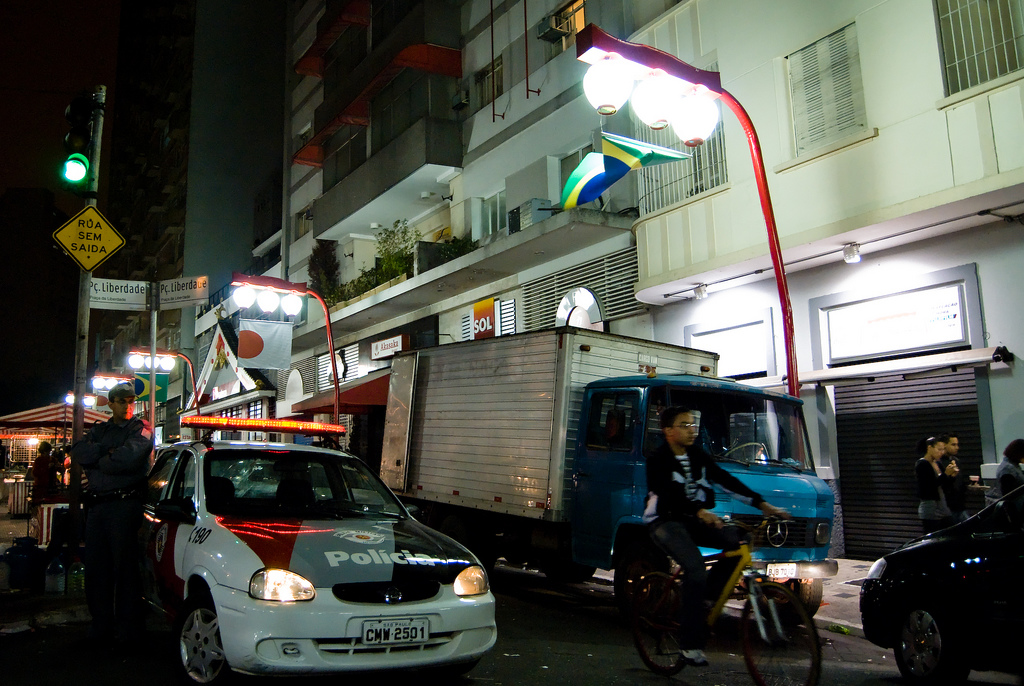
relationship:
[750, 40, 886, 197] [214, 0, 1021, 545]
window on building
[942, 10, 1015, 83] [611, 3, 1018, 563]
window on building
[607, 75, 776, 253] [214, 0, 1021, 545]
window on building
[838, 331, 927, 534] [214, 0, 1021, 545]
window on building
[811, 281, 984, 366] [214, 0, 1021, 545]
window on building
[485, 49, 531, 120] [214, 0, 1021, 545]
window on building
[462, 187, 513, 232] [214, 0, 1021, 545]
window on building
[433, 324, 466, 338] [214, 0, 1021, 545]
window on building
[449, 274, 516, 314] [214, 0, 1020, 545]
window on building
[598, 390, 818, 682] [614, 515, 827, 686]
man on bike